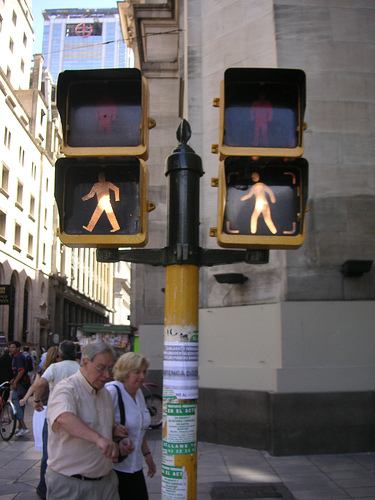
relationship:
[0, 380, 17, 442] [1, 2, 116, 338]
bike parked near building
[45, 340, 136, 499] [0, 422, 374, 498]
man walking on sidewalk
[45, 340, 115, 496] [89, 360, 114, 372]
man wearing eyeglasses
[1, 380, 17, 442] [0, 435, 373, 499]
bike on sidewalk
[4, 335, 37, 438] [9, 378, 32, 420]
man wearing shorts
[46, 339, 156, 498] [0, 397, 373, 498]
couple walking on city sidewalk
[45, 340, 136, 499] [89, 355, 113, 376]
man wearing eye glass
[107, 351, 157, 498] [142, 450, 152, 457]
woman wearing wrist watch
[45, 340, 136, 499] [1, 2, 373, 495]
man walking city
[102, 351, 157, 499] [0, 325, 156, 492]
woman minding business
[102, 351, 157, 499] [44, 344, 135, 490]
woman walking man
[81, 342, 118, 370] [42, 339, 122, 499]
head of man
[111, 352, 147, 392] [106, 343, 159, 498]
head of woman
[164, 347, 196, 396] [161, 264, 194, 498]
stickers on pole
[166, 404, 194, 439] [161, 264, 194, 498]
stickers on pole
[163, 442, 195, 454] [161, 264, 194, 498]
stickers on pole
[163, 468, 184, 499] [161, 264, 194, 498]
stickers on pole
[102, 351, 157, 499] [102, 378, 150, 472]
woman wearing shirt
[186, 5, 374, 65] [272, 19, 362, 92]
building has blocks